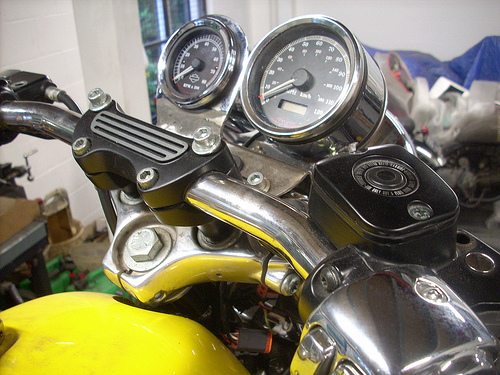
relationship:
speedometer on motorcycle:
[240, 15, 366, 141] [1, 14, 498, 374]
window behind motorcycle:
[135, 1, 209, 126] [1, 14, 498, 374]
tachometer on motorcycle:
[157, 18, 237, 110] [1, 14, 498, 374]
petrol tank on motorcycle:
[2, 290, 257, 374] [1, 14, 498, 374]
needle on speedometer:
[257, 77, 294, 98] [240, 15, 366, 141]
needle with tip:
[257, 77, 294, 98] [257, 94, 261, 100]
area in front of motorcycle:
[352, 1, 499, 208] [1, 14, 498, 374]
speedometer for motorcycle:
[240, 15, 366, 141] [1, 14, 498, 374]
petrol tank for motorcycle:
[2, 290, 257, 374] [1, 14, 498, 374]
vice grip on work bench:
[0, 147, 39, 182] [1, 197, 55, 297]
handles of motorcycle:
[0, 66, 497, 373] [1, 14, 498, 374]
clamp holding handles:
[74, 90, 242, 227] [0, 66, 497, 373]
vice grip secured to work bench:
[0, 147, 39, 182] [1, 197, 55, 297]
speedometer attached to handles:
[240, 15, 366, 141] [0, 66, 497, 373]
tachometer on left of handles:
[157, 18, 237, 110] [0, 66, 497, 373]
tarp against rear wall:
[361, 35, 499, 89] [250, 1, 499, 60]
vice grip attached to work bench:
[0, 147, 39, 182] [1, 197, 55, 297]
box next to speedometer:
[308, 144, 459, 269] [240, 15, 366, 141]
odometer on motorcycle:
[277, 98, 309, 116] [1, 14, 498, 374]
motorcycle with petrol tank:
[1, 14, 498, 374] [2, 290, 257, 374]